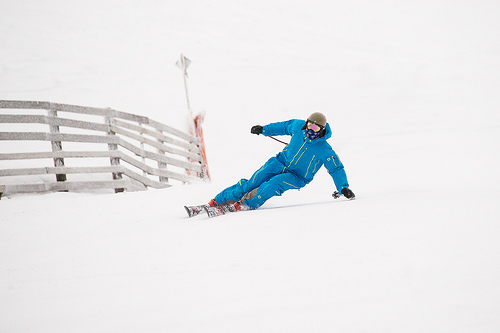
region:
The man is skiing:
[150, 73, 396, 294]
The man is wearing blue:
[196, 91, 375, 328]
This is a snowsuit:
[208, 93, 415, 294]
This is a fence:
[15, 85, 237, 200]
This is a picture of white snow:
[73, 192, 353, 329]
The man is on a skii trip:
[199, 110, 466, 327]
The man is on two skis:
[146, 157, 361, 304]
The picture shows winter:
[53, 42, 438, 324]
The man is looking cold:
[210, 68, 408, 300]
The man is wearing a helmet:
[291, 112, 341, 177]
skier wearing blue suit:
[200, 103, 365, 215]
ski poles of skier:
[258, 133, 350, 204]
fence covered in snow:
[7, 93, 211, 189]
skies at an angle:
[178, 191, 233, 222]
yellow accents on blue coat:
[282, 125, 339, 190]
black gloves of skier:
[247, 124, 356, 201]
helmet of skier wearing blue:
[305, 115, 329, 130]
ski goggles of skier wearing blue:
[299, 117, 322, 134]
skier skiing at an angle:
[160, 100, 352, 225]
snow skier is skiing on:
[7, 157, 497, 329]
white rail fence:
[0, 97, 212, 187]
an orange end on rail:
[191, 103, 213, 195]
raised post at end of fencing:
[165, 44, 199, 139]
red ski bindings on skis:
[202, 186, 247, 214]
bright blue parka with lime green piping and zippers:
[263, 112, 348, 189]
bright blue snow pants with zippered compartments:
[206, 151, 298, 208]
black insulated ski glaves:
[250, 118, 263, 137]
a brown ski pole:
[257, 130, 297, 150]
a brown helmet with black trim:
[304, 111, 329, 133]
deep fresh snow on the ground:
[4, 215, 496, 327]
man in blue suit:
[188, 111, 354, 211]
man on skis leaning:
[187, 114, 355, 214]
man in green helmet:
[195, 113, 360, 207]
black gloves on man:
[342, 189, 352, 197]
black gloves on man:
[251, 125, 265, 133]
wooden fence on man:
[0, 119, 200, 193]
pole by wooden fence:
[175, 58, 211, 180]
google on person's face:
[307, 119, 323, 131]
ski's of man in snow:
[186, 195, 246, 217]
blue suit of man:
[220, 128, 327, 208]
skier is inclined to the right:
[179, 103, 357, 230]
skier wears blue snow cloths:
[183, 103, 368, 225]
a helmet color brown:
[268, 99, 344, 160]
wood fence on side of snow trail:
[0, 92, 212, 196]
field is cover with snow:
[4, 0, 493, 330]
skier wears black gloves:
[229, 98, 367, 214]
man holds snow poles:
[236, 97, 367, 202]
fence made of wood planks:
[2, 94, 207, 193]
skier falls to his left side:
[168, 100, 359, 225]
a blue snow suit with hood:
[211, 108, 348, 212]